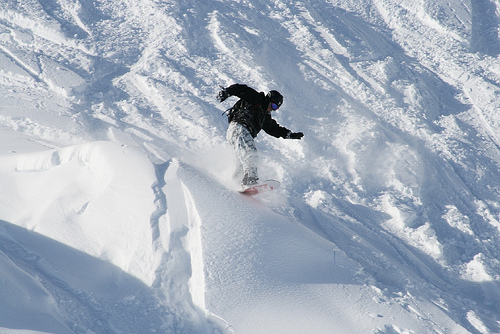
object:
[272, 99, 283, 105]
goggles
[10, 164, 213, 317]
mound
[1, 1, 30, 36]
snow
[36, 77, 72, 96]
tracks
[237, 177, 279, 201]
snowboard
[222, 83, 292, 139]
jacket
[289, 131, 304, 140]
glove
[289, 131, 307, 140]
left hand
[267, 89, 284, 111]
hat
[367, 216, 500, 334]
downhill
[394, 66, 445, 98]
snow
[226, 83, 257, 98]
arms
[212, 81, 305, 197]
person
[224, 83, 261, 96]
sleeves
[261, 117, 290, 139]
sleeves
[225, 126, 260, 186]
pants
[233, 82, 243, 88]
elbow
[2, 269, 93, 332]
shadow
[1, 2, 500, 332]
mountain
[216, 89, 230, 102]
gloves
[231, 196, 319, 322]
slope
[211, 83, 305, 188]
boy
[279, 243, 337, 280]
shadows